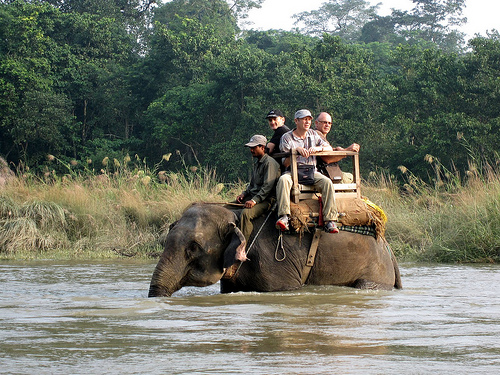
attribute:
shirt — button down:
[235, 162, 280, 208]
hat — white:
[286, 102, 326, 125]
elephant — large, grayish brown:
[145, 197, 405, 302]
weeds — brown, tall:
[18, 175, 136, 248]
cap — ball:
[263, 108, 283, 115]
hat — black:
[264, 106, 289, 119]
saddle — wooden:
[242, 137, 401, 240]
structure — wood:
[279, 141, 365, 205]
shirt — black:
[263, 124, 293, 153]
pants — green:
[223, 197, 278, 247]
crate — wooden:
[268, 142, 371, 200]